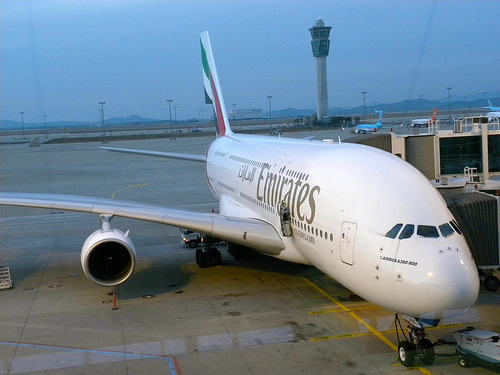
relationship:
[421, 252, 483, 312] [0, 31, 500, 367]
nose of airplane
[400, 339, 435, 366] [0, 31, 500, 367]
wheels in front of airplane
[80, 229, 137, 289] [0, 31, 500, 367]
engine` on airplane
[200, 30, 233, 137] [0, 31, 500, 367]
tail of airplane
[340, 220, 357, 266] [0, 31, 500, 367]
door on airplane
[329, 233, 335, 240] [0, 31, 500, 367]
window on airplane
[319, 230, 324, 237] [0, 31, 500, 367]
window on airplane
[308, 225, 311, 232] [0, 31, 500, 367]
window on airplane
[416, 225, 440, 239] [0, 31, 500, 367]
window in front of airplane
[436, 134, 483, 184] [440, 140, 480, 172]
cart for luggage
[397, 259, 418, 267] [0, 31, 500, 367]
numbers on front of airplane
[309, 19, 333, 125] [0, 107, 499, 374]
tower of airport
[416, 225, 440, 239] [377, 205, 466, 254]
window of cockpit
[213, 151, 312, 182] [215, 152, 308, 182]
row of windows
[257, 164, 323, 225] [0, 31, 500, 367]
name on airplane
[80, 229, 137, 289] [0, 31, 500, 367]
engine of airplane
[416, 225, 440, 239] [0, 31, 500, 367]
window on airplane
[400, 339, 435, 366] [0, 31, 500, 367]
wheels of airplane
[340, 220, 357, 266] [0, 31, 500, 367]
door to airplane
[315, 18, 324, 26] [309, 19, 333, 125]
top of tower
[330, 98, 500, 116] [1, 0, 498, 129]
hill in distance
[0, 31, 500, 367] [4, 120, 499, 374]
airplane in foreground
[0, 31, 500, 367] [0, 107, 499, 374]
airplane on airport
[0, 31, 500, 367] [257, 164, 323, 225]
airplane has name